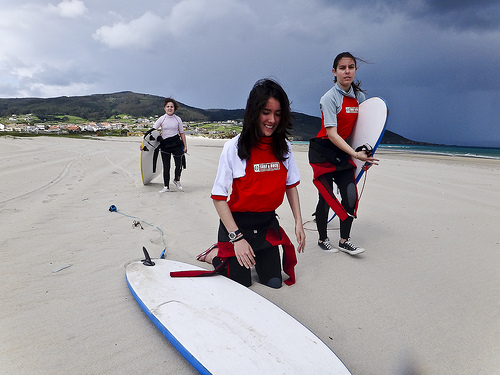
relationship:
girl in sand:
[210, 76, 311, 294] [3, 131, 499, 374]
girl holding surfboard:
[302, 45, 382, 265] [334, 86, 390, 185]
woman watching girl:
[153, 95, 192, 196] [210, 76, 311, 294]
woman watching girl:
[153, 95, 192, 196] [302, 45, 382, 265]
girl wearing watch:
[210, 76, 311, 294] [226, 229, 245, 240]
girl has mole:
[210, 76, 311, 294] [263, 131, 269, 136]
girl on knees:
[210, 76, 311, 294] [237, 273, 288, 291]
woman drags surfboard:
[153, 95, 192, 196] [138, 124, 161, 190]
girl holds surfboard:
[302, 45, 382, 265] [334, 86, 390, 185]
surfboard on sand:
[117, 242, 354, 374] [3, 131, 499, 374]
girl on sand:
[210, 76, 311, 294] [3, 131, 499, 374]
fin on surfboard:
[138, 242, 155, 268] [117, 242, 354, 374]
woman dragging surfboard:
[153, 95, 192, 196] [138, 124, 161, 190]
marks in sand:
[0, 152, 81, 202] [3, 131, 499, 374]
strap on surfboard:
[166, 262, 226, 279] [117, 242, 354, 374]